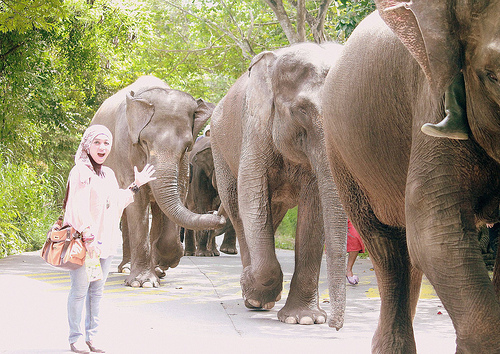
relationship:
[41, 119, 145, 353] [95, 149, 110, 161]
woman with mouth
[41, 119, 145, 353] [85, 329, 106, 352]
woman has shoe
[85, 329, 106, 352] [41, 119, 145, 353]
shoe of woman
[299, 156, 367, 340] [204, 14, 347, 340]
trunk of elephant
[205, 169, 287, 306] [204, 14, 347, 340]
leg of elephant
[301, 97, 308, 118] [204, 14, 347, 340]
eye of elephant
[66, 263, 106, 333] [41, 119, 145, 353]
jeans on woman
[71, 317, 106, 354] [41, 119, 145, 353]
shoes on woman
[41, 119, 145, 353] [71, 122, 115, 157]
woman with scarf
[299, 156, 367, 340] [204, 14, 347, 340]
trunk on elephant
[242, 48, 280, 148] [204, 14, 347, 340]
ear on elephant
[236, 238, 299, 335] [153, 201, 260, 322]
foot on concrete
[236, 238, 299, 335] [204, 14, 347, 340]
foot of elephant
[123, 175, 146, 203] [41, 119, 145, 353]
bracelet on woman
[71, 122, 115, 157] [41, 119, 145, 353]
scarf on woman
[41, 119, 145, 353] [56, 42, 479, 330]
woman buy elephants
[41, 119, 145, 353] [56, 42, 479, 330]
woman by elephants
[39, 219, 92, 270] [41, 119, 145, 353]
bag of woman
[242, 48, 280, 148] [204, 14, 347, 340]
ear of elephant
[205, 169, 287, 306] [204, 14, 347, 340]
leg on elephant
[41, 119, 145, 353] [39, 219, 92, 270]
woman with bag